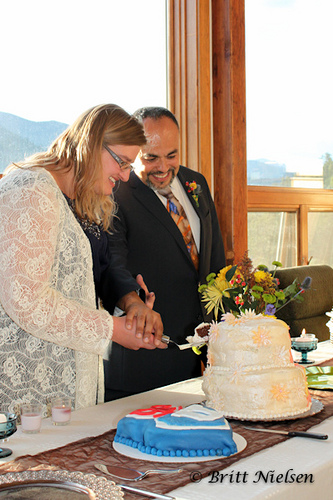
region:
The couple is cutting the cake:
[174, 307, 305, 429]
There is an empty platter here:
[8, 452, 125, 497]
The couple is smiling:
[27, 99, 229, 239]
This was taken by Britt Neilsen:
[179, 448, 331, 485]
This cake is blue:
[95, 396, 245, 484]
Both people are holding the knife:
[102, 281, 190, 368]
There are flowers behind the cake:
[174, 248, 322, 321]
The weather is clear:
[108, 23, 327, 204]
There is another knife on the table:
[239, 417, 324, 441]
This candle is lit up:
[46, 395, 88, 426]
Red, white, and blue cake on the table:
[106, 401, 239, 458]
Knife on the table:
[241, 421, 327, 441]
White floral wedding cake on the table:
[201, 307, 322, 420]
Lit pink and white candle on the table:
[45, 394, 76, 424]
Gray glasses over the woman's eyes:
[97, 142, 137, 170]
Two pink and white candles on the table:
[13, 393, 77, 431]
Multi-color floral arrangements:
[188, 247, 309, 313]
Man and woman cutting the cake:
[0, 91, 322, 419]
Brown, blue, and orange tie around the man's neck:
[154, 184, 202, 275]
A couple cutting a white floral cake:
[3, 105, 326, 418]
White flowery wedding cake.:
[206, 311, 315, 419]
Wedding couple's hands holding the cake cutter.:
[106, 291, 174, 355]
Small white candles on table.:
[13, 395, 84, 434]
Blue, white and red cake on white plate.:
[103, 396, 249, 461]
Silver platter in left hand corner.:
[0, 467, 124, 499]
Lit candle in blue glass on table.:
[288, 327, 317, 365]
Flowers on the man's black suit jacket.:
[186, 176, 203, 205]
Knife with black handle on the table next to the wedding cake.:
[243, 423, 330, 441]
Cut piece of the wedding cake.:
[188, 320, 215, 345]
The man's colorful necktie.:
[165, 186, 201, 272]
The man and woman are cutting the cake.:
[48, 85, 322, 476]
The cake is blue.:
[111, 376, 248, 474]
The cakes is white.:
[183, 270, 305, 423]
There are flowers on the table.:
[203, 248, 330, 386]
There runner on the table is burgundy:
[38, 432, 116, 495]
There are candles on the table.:
[15, 393, 73, 432]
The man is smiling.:
[131, 106, 201, 194]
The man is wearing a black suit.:
[136, 163, 216, 363]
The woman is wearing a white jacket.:
[3, 173, 100, 434]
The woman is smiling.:
[74, 162, 193, 216]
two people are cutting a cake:
[3, 86, 319, 463]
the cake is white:
[195, 295, 322, 436]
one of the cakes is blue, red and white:
[103, 391, 244, 477]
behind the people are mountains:
[0, 107, 332, 195]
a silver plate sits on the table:
[1, 463, 127, 499]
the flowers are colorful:
[186, 248, 313, 365]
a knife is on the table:
[241, 417, 329, 456]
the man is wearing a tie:
[93, 101, 273, 397]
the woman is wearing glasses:
[20, 94, 160, 232]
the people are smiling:
[47, 93, 220, 229]